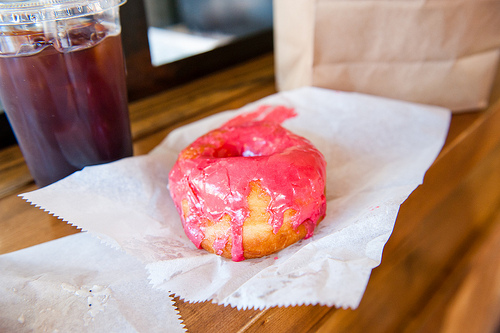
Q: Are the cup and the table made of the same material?
A: No, the cup is made of plastic and the table is made of wood.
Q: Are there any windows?
A: Yes, there is a window.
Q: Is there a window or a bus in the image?
A: Yes, there is a window.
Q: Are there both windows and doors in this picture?
A: No, there is a window but no doors.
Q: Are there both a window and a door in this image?
A: No, there is a window but no doors.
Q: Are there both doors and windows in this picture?
A: No, there is a window but no doors.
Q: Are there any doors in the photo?
A: No, there are no doors.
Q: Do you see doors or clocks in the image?
A: No, there are no doors or clocks.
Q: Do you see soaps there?
A: No, there are no soaps.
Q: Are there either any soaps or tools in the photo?
A: No, there are no soaps or tools.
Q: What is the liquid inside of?
A: The liquid is inside the cup.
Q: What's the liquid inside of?
A: The liquid is inside the cup.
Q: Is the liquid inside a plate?
A: No, the liquid is inside the cup.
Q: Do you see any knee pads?
A: No, there are no knee pads.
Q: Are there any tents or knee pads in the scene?
A: No, there are no knee pads or tents.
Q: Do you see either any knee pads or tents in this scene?
A: No, there are no knee pads or tents.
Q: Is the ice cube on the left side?
A: Yes, the ice cube is on the left of the image.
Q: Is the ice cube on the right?
A: No, the ice cube is on the left of the image.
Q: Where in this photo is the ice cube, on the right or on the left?
A: The ice cube is on the left of the image.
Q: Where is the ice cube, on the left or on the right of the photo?
A: The ice cube is on the left of the image.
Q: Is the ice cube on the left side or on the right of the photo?
A: The ice cube is on the left of the image.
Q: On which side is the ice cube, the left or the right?
A: The ice cube is on the left of the image.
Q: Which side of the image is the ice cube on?
A: The ice cube is on the left of the image.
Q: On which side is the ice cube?
A: The ice cube is on the left of the image.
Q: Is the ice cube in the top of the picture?
A: Yes, the ice cube is in the top of the image.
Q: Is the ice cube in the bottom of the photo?
A: No, the ice cube is in the top of the image.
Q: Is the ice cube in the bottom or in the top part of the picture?
A: The ice cube is in the top of the image.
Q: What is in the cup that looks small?
A: The ice cube is in the cup.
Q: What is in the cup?
A: The ice cube is in the cup.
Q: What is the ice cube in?
A: The ice cube is in the cup.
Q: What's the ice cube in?
A: The ice cube is in the cup.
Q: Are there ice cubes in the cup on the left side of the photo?
A: Yes, there is an ice cube in the cup.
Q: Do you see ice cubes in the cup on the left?
A: Yes, there is an ice cube in the cup.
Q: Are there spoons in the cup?
A: No, there is an ice cube in the cup.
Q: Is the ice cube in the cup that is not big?
A: Yes, the ice cube is in the cup.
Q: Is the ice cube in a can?
A: No, the ice cube is in the cup.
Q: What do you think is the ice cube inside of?
A: The ice cube is inside the cup.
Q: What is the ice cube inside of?
A: The ice cube is inside the cup.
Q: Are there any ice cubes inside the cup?
A: Yes, there is an ice cube inside the cup.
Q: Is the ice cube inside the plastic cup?
A: Yes, the ice cube is inside the cup.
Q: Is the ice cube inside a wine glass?
A: No, the ice cube is inside the cup.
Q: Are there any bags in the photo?
A: Yes, there is a bag.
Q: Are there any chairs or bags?
A: Yes, there is a bag.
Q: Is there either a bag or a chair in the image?
A: Yes, there is a bag.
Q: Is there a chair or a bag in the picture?
A: Yes, there is a bag.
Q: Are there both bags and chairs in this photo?
A: No, there is a bag but no chairs.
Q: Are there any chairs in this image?
A: No, there are no chairs.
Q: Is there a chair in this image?
A: No, there are no chairs.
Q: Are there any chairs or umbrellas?
A: No, there are no chairs or umbrellas.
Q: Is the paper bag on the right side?
A: Yes, the bag is on the right of the image.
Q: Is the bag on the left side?
A: No, the bag is on the right of the image.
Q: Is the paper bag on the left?
A: No, the bag is on the right of the image.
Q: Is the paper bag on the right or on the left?
A: The bag is on the right of the image.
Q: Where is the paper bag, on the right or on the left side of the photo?
A: The bag is on the right of the image.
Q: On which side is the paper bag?
A: The bag is on the right of the image.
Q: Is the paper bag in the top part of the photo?
A: Yes, the bag is in the top of the image.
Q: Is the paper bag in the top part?
A: Yes, the bag is in the top of the image.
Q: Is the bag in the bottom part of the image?
A: No, the bag is in the top of the image.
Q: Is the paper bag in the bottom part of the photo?
A: No, the bag is in the top of the image.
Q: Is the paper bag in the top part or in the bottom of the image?
A: The bag is in the top of the image.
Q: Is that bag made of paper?
A: Yes, the bag is made of paper.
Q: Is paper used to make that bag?
A: Yes, the bag is made of paper.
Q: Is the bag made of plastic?
A: No, the bag is made of paper.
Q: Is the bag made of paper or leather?
A: The bag is made of paper.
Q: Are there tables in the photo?
A: Yes, there is a table.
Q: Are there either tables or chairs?
A: Yes, there is a table.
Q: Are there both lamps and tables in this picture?
A: No, there is a table but no lamps.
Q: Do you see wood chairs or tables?
A: Yes, there is a wood table.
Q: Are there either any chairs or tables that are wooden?
A: Yes, the table is wooden.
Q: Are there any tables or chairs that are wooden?
A: Yes, the table is wooden.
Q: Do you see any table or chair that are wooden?
A: Yes, the table is wooden.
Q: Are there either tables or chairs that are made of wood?
A: Yes, the table is made of wood.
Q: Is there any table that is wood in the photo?
A: Yes, there is a wood table.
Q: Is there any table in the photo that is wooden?
A: Yes, there is a table that is wooden.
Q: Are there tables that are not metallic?
A: Yes, there is a wooden table.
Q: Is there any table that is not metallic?
A: Yes, there is a wooden table.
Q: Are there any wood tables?
A: Yes, there is a table that is made of wood.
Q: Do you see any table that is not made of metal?
A: Yes, there is a table that is made of wood.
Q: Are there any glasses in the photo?
A: No, there are no glasses.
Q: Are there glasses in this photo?
A: No, there are no glasses.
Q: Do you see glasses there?
A: No, there are no glasses.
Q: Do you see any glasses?
A: No, there are no glasses.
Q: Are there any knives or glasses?
A: No, there are no glasses or knives.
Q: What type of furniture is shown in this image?
A: The furniture is a table.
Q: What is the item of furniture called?
A: The piece of furniture is a table.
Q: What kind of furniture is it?
A: The piece of furniture is a table.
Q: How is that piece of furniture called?
A: This is a table.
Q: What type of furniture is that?
A: This is a table.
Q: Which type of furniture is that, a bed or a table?
A: This is a table.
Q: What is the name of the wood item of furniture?
A: The piece of furniture is a table.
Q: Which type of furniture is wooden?
A: The furniture is a table.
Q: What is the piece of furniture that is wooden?
A: The piece of furniture is a table.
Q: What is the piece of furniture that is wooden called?
A: The piece of furniture is a table.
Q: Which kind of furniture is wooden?
A: The furniture is a table.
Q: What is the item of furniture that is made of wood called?
A: The piece of furniture is a table.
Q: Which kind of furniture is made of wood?
A: The furniture is a table.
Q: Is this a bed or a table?
A: This is a table.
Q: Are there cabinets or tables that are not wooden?
A: No, there is a table but it is wooden.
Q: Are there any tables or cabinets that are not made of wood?
A: No, there is a table but it is made of wood.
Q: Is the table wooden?
A: Yes, the table is wooden.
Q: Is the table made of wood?
A: Yes, the table is made of wood.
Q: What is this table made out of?
A: The table is made of wood.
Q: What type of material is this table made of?
A: The table is made of wood.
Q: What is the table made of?
A: The table is made of wood.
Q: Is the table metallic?
A: No, the table is wooden.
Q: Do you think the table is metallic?
A: No, the table is wooden.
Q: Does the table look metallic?
A: No, the table is wooden.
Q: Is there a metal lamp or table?
A: No, there is a table but it is wooden.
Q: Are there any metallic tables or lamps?
A: No, there is a table but it is wooden.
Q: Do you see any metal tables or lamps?
A: No, there is a table but it is wooden.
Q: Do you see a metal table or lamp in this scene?
A: No, there is a table but it is wooden.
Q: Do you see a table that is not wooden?
A: No, there is a table but it is wooden.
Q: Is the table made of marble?
A: No, the table is made of wood.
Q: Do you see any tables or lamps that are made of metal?
A: No, there is a table but it is made of wood.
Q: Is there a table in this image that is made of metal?
A: No, there is a table but it is made of wood.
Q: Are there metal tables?
A: No, there is a table but it is made of wood.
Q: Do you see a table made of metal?
A: No, there is a table but it is made of wood.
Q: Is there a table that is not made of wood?
A: No, there is a table but it is made of wood.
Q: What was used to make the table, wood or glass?
A: The table is made of wood.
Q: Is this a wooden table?
A: Yes, this is a wooden table.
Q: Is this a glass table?
A: No, this is a wooden table.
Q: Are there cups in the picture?
A: Yes, there is a cup.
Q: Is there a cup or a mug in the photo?
A: Yes, there is a cup.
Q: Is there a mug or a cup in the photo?
A: Yes, there is a cup.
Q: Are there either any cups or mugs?
A: Yes, there is a cup.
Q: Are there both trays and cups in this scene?
A: No, there is a cup but no trays.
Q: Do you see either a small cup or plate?
A: Yes, there is a small cup.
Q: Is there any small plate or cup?
A: Yes, there is a small cup.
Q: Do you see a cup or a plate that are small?
A: Yes, the cup is small.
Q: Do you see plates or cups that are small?
A: Yes, the cup is small.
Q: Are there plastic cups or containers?
A: Yes, there is a plastic cup.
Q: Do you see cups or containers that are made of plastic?
A: Yes, the cup is made of plastic.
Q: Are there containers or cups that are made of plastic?
A: Yes, the cup is made of plastic.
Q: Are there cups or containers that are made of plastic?
A: Yes, the cup is made of plastic.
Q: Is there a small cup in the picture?
A: Yes, there is a small cup.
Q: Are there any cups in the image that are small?
A: Yes, there is a cup that is small.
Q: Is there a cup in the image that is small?
A: Yes, there is a cup that is small.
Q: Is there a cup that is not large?
A: Yes, there is a small cup.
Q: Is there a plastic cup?
A: Yes, there is a cup that is made of plastic.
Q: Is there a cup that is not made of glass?
A: Yes, there is a cup that is made of plastic.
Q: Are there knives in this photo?
A: No, there are no knives.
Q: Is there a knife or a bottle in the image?
A: No, there are no knives or bottles.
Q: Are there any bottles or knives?
A: No, there are no knives or bottles.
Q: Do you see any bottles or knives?
A: No, there are no knives or bottles.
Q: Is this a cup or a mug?
A: This is a cup.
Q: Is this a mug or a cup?
A: This is a cup.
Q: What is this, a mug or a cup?
A: This is a cup.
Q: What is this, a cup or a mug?
A: This is a cup.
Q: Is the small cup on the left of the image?
A: Yes, the cup is on the left of the image.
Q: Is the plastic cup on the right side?
A: No, the cup is on the left of the image.